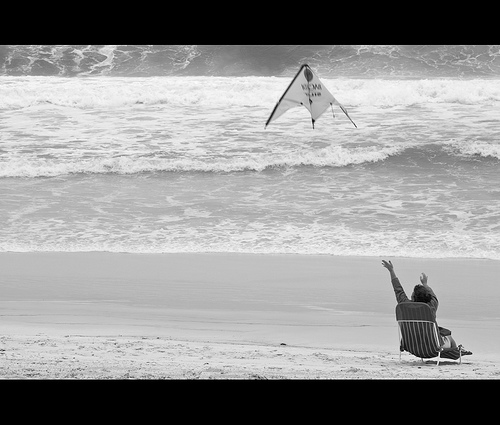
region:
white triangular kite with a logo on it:
[263, 62, 356, 132]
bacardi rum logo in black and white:
[300, 66, 324, 99]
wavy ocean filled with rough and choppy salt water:
[0, 42, 499, 261]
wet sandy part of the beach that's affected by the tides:
[0, 252, 499, 361]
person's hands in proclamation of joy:
[379, 257, 439, 309]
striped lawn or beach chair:
[392, 300, 472, 369]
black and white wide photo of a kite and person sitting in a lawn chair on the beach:
[0, 42, 499, 384]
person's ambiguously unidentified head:
[408, 283, 435, 305]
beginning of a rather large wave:
[0, 44, 499, 79]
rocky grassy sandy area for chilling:
[0, 332, 499, 381]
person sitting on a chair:
[372, 248, 482, 370]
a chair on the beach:
[358, 246, 482, 365]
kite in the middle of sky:
[264, 55, 363, 137]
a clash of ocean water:
[60, 142, 485, 266]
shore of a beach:
[50, 203, 486, 259]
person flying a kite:
[270, 50, 484, 357]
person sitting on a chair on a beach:
[373, 251, 484, 369]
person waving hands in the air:
[365, 244, 485, 364]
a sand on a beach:
[52, 338, 344, 389]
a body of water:
[37, 75, 221, 129]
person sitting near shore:
[375, 247, 476, 377]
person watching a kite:
[257, 43, 484, 379]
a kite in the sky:
[253, 43, 401, 175]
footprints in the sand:
[111, 349, 172, 374]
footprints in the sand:
[53, 353, 106, 388]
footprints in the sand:
[7, 331, 47, 383]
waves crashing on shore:
[268, 138, 326, 190]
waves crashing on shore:
[182, 138, 233, 184]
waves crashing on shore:
[107, 131, 167, 185]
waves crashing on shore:
[7, 127, 92, 183]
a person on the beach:
[365, 251, 487, 379]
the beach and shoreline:
[40, 322, 362, 379]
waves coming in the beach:
[29, 132, 493, 247]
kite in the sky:
[255, 53, 383, 135]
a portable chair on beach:
[396, 312, 488, 382]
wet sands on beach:
[32, 252, 313, 296]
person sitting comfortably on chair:
[372, 248, 487, 376]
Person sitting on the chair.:
[375, 245, 475, 362]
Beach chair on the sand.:
[390, 297, 475, 363]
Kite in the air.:
[260, 55, 356, 131]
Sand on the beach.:
[0, 250, 495, 380]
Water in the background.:
[0, 45, 495, 260]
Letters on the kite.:
[295, 80, 320, 100]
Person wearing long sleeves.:
[377, 252, 444, 330]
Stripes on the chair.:
[392, 300, 458, 365]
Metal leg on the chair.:
[395, 343, 444, 368]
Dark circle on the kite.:
[300, 65, 317, 81]